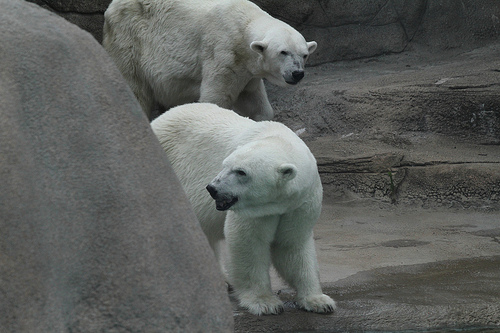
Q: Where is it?
A: This is at the zoo.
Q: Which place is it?
A: It is a zoo.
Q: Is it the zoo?
A: Yes, it is the zoo.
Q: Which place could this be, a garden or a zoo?
A: It is a zoo.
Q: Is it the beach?
A: No, it is the zoo.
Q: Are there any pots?
A: No, there are no pots.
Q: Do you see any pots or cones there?
A: No, there are no pots or cones.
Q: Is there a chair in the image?
A: No, there are no chairs.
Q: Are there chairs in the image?
A: No, there are no chairs.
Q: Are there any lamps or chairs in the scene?
A: No, there are no chairs or lamps.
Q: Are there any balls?
A: No, there are no balls.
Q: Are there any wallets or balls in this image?
A: No, there are no balls or wallets.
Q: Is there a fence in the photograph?
A: No, there are no fences.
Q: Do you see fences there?
A: No, there are no fences.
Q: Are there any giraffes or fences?
A: No, there are no fences or giraffes.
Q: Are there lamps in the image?
A: No, there are no lamps.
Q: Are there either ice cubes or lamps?
A: No, there are no lamps or ice cubes.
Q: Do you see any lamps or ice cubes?
A: No, there are no lamps or ice cubes.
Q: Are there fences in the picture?
A: No, there are no fences.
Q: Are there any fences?
A: No, there are no fences.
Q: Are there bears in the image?
A: Yes, there is a bear.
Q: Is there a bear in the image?
A: Yes, there is a bear.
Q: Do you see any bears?
A: Yes, there is a bear.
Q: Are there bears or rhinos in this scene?
A: Yes, there is a bear.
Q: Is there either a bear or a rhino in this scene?
A: Yes, there is a bear.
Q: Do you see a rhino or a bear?
A: Yes, there is a bear.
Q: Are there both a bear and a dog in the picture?
A: No, there is a bear but no dogs.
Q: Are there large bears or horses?
A: Yes, there is a large bear.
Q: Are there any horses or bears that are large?
A: Yes, the bear is large.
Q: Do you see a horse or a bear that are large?
A: Yes, the bear is large.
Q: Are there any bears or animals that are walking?
A: Yes, the bear is walking.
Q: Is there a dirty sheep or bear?
A: Yes, there is a dirty bear.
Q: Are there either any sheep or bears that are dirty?
A: Yes, the bear is dirty.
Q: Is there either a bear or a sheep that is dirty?
A: Yes, the bear is dirty.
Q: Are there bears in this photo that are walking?
A: Yes, there is a bear that is walking.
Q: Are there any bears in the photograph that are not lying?
A: Yes, there is a bear that is walking.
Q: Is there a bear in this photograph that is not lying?
A: Yes, there is a bear that is walking.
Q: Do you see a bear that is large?
A: Yes, there is a large bear.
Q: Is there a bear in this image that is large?
A: Yes, there is a bear that is large.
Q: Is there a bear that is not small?
A: Yes, there is a large bear.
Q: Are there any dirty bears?
A: Yes, there is a dirty bear.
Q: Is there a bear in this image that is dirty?
A: Yes, there is a bear that is dirty.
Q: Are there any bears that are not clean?
A: Yes, there is a dirty bear.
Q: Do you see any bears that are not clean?
A: Yes, there is a dirty bear.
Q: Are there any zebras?
A: No, there are no zebras.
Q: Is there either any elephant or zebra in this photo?
A: No, there are no zebras or elephants.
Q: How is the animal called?
A: The animal is a bear.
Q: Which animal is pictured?
A: The animal is a bear.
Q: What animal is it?
A: The animal is a bear.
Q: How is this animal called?
A: This is a bear.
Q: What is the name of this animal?
A: This is a bear.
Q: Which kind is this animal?
A: This is a bear.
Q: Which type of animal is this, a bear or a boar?
A: This is a bear.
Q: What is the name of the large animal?
A: The animal is a bear.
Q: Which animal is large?
A: The animal is a bear.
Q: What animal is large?
A: The animal is a bear.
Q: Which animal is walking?
A: The animal is a bear.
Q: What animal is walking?
A: The animal is a bear.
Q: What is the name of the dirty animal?
A: The animal is a bear.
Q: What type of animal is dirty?
A: The animal is a bear.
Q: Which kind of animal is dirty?
A: The animal is a bear.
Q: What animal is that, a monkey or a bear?
A: That is a bear.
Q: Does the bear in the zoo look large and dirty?
A: Yes, the bear is large and dirty.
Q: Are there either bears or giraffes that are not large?
A: No, there is a bear but it is large.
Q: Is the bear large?
A: Yes, the bear is large.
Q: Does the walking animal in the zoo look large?
A: Yes, the bear is large.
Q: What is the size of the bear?
A: The bear is large.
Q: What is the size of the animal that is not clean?
A: The bear is large.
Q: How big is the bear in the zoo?
A: The bear is large.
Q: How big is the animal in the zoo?
A: The bear is large.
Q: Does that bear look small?
A: No, the bear is large.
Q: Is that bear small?
A: No, the bear is large.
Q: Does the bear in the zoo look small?
A: No, the bear is large.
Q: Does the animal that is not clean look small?
A: No, the bear is large.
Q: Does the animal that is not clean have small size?
A: No, the bear is large.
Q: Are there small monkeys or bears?
A: No, there is a bear but it is large.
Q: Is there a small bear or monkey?
A: No, there is a bear but it is large.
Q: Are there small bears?
A: No, there is a bear but it is large.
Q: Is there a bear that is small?
A: No, there is a bear but it is large.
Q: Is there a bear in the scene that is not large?
A: No, there is a bear but it is large.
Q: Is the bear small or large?
A: The bear is large.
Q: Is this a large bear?
A: Yes, this is a large bear.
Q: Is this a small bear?
A: No, this is a large bear.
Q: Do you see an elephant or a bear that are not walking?
A: No, there is a bear but it is walking.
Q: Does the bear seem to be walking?
A: Yes, the bear is walking.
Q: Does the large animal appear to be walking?
A: Yes, the bear is walking.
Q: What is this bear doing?
A: The bear is walking.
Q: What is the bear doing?
A: The bear is walking.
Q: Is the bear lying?
A: No, the bear is walking.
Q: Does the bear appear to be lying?
A: No, the bear is walking.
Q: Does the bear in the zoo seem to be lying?
A: No, the bear is walking.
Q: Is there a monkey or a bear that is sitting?
A: No, there is a bear but it is walking.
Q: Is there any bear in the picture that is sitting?
A: No, there is a bear but it is walking.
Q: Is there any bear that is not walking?
A: No, there is a bear but it is walking.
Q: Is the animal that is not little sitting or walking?
A: The bear is walking.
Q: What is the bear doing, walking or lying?
A: The bear is walking.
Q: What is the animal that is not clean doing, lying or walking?
A: The bear is walking.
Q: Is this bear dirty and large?
A: Yes, the bear is dirty and large.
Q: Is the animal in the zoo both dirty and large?
A: Yes, the bear is dirty and large.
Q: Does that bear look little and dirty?
A: No, the bear is dirty but large.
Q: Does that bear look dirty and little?
A: No, the bear is dirty but large.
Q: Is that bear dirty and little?
A: No, the bear is dirty but large.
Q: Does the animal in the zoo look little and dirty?
A: No, the bear is dirty but large.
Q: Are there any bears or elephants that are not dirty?
A: No, there is a bear but it is dirty.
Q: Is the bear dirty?
A: Yes, the bear is dirty.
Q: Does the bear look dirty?
A: Yes, the bear is dirty.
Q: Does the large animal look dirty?
A: Yes, the bear is dirty.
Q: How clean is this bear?
A: The bear is dirty.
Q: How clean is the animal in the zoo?
A: The bear is dirty.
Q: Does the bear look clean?
A: No, the bear is dirty.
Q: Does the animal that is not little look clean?
A: No, the bear is dirty.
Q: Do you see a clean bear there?
A: No, there is a bear but it is dirty.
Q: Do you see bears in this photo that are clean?
A: No, there is a bear but it is dirty.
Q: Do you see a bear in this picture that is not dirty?
A: No, there is a bear but it is dirty.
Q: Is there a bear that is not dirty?
A: No, there is a bear but it is dirty.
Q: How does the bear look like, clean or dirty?
A: The bear is dirty.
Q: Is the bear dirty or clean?
A: The bear is dirty.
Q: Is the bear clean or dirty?
A: The bear is dirty.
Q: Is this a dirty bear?
A: Yes, this is a dirty bear.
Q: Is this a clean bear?
A: No, this is a dirty bear.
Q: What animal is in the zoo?
A: The bear is in the zoo.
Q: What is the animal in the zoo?
A: The animal is a bear.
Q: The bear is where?
A: The bear is in the zoo.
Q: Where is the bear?
A: The bear is in the zoo.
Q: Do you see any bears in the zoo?
A: Yes, there is a bear in the zoo.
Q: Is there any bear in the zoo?
A: Yes, there is a bear in the zoo.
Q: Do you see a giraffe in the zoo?
A: No, there is a bear in the zoo.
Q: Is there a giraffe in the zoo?
A: No, there is a bear in the zoo.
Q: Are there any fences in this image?
A: No, there are no fences.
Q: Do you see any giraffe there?
A: No, there are no giraffes.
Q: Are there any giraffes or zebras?
A: No, there are no giraffes or zebras.